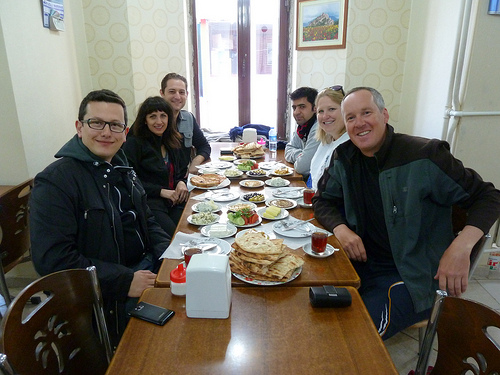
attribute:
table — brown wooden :
[153, 226, 363, 286]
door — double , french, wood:
[199, 1, 284, 143]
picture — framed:
[293, 3, 352, 54]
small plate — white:
[302, 240, 337, 260]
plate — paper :
[227, 228, 309, 291]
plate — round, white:
[191, 216, 288, 237]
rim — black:
[85, 117, 125, 133]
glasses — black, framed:
[78, 117, 126, 134]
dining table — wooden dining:
[113, 140, 393, 374]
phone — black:
[127, 300, 176, 325]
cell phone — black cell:
[118, 282, 185, 331]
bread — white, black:
[237, 231, 284, 259]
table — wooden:
[109, 140, 398, 373]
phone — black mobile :
[127, 300, 190, 326]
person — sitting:
[122, 95, 187, 235]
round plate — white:
[210, 227, 285, 290]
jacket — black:
[30, 142, 172, 305]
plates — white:
[166, 146, 330, 261]